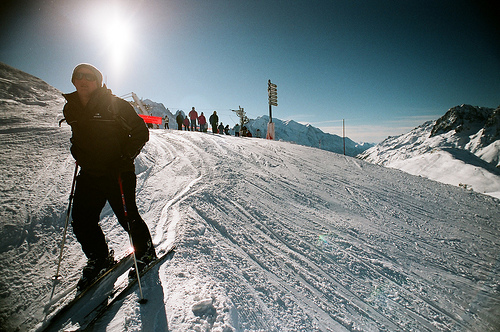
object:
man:
[59, 63, 157, 287]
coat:
[63, 83, 151, 173]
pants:
[70, 159, 155, 256]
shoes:
[83, 252, 116, 277]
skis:
[57, 245, 174, 331]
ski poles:
[117, 171, 146, 299]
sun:
[57, 0, 155, 73]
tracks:
[152, 137, 200, 243]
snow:
[0, 62, 499, 331]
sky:
[0, 0, 500, 146]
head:
[70, 63, 104, 96]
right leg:
[69, 170, 109, 258]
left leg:
[107, 167, 155, 259]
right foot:
[83, 251, 117, 282]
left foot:
[128, 243, 159, 279]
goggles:
[72, 72, 96, 81]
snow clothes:
[60, 85, 156, 260]